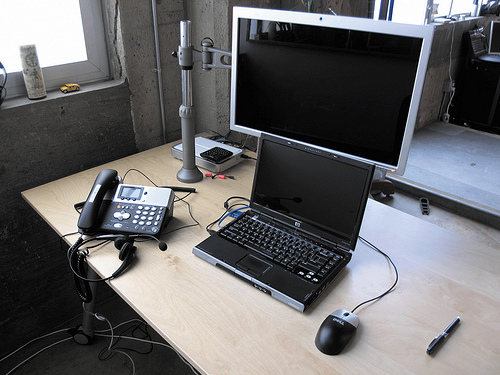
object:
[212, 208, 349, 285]
keyboard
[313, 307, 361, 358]
mouse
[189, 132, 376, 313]
laptop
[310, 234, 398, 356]
mouse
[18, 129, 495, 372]
desk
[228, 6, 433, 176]
monitor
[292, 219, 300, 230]
logo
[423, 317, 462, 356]
pen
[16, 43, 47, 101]
candle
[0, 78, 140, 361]
window sill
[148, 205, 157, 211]
button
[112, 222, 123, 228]
button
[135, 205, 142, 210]
button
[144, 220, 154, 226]
button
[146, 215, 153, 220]
button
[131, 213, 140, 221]
button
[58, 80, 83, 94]
car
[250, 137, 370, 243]
screen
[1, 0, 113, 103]
window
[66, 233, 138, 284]
head phones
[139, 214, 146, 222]
button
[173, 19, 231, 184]
computer stand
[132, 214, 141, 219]
button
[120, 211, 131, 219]
button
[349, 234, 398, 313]
cord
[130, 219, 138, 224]
button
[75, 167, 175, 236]
phone